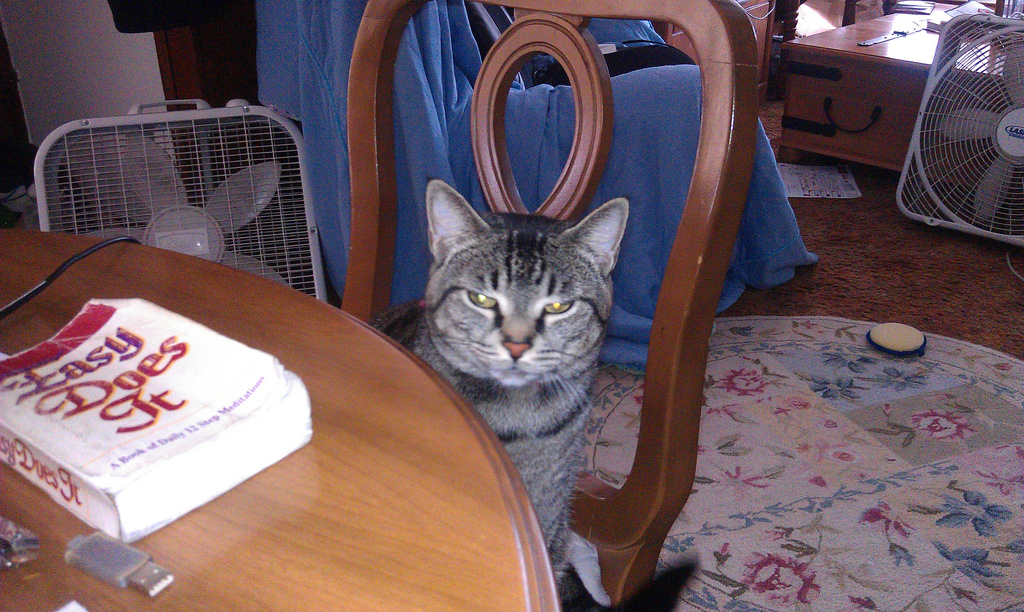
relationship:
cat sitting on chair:
[372, 178, 698, 611] [341, 2, 761, 611]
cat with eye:
[372, 178, 698, 611] [467, 290, 499, 311]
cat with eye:
[372, 178, 698, 611] [541, 296, 576, 316]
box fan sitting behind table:
[32, 98, 329, 304] [1, 229, 561, 611]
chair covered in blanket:
[333, 3, 757, 305] [254, 0, 817, 367]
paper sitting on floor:
[776, 157, 864, 199] [715, 158, 1022, 360]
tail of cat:
[559, 558, 702, 610] [372, 178, 698, 611]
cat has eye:
[372, 178, 698, 611] [467, 290, 499, 311]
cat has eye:
[372, 178, 698, 611] [541, 296, 576, 316]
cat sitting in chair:
[372, 178, 698, 611] [341, 2, 761, 611]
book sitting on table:
[0, 297, 314, 545] [1, 229, 561, 611]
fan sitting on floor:
[895, 15, 1023, 249] [715, 158, 1022, 360]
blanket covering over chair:
[254, 0, 817, 367] [333, 3, 757, 305]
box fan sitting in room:
[32, 98, 329, 304] [1, 2, 1022, 611]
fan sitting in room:
[895, 15, 1023, 249] [1, 2, 1022, 611]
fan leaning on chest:
[895, 15, 1023, 249] [778, 12, 1022, 193]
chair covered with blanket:
[333, 3, 757, 305] [254, 0, 817, 367]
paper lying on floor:
[776, 157, 864, 199] [715, 158, 1022, 360]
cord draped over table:
[0, 233, 139, 316] [1, 229, 561, 611]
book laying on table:
[0, 297, 314, 545] [1, 229, 561, 611]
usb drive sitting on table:
[64, 533, 177, 597] [1, 229, 561, 611]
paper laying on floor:
[776, 157, 864, 199] [715, 158, 1022, 360]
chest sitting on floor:
[778, 12, 1022, 193] [715, 158, 1022, 360]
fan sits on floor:
[895, 15, 1023, 249] [715, 158, 1022, 360]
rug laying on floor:
[580, 314, 1022, 611] [715, 158, 1022, 360]